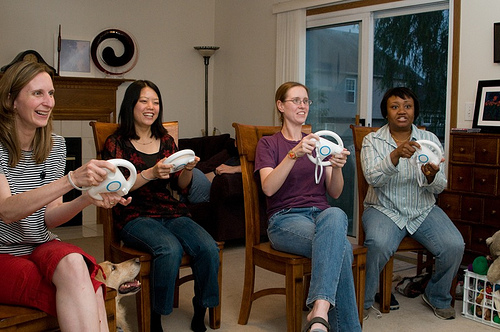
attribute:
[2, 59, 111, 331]
woman — sitting, playing, smiling, happy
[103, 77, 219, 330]
woman — sitting, playing, smiling, happy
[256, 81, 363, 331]
woman — playing, smiling, happy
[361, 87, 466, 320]
woman — playing, smiling, happy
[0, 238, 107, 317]
shorts — red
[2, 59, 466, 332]
women — playing, laughing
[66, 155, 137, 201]
game controller — white, wheel shaped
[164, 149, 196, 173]
game controller — white, wheel shaped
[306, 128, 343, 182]
game controller — white, wheel shaped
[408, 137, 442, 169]
game controller — white, wheel shaped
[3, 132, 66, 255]
shirt — striped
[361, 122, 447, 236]
shirt — striped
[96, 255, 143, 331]
dog — looking up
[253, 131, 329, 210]
tee shirt — purple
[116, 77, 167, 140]
hair — black, short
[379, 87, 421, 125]
hair — black, short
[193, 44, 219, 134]
lamp — tall, modern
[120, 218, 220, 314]
jeans — blue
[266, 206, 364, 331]
jeans — blue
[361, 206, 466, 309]
jeans — blue